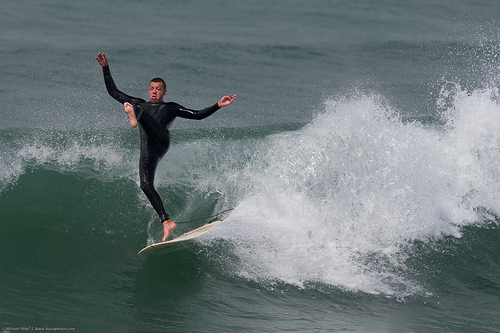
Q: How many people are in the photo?
A: One.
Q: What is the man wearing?
A: Wetsuit.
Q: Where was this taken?
A: Ocean.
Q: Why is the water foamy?
A: Waves.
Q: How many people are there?
A: 1.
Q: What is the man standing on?
A: Surfboard.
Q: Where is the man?
A: Standing on a surfboard.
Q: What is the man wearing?
A: Wetsuit.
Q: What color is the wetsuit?
A: Black.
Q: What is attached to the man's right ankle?
A: Cord.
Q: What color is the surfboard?
A: White.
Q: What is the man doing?
A: Surfing.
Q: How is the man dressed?
A: In a black wetsuit.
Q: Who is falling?
A: The surfer.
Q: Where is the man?
A: The ocean.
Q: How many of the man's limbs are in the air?
A: Three.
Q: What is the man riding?
A: Surfboard.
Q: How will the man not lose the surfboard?
A: He is tethered to it.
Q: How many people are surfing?
A: One.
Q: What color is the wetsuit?
A: Black.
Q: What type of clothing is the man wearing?
A: Wetsuit.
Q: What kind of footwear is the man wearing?
A: None.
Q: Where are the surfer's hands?
A: In the air.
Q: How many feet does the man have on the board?
A: 1.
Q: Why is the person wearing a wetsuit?
A: The person is surfing.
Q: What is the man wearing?
A: A wetsuit.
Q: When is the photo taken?
A: During the daytime.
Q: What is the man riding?
A: A surfboard.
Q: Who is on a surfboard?
A: A man.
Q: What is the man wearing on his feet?
A: Nothing.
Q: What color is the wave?
A: White.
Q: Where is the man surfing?
A: In the ocean.